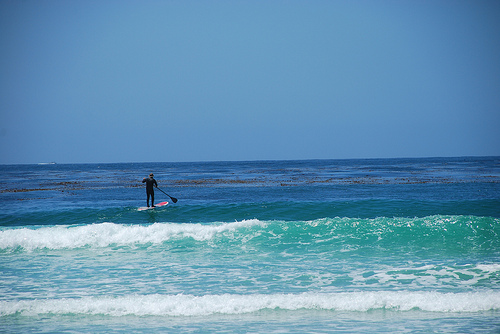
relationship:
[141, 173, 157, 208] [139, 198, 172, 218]
man standing on board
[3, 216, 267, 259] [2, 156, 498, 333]
sea foam in ocean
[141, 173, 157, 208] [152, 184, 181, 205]
man using paddle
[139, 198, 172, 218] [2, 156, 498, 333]
board floating on ocean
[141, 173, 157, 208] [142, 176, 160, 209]
man has wet suit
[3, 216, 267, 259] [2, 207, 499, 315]
sea foam on top of wave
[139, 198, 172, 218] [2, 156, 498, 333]
board on top of ocean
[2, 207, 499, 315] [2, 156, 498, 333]
wave crashing back into ocean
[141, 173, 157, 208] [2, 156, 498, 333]
man boarding on ocean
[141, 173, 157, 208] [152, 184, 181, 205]
man holding paddle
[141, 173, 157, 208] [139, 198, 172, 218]
man on top of board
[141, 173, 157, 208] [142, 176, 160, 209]
man dressed in wet suit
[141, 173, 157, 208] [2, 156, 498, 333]
man on top of ocean